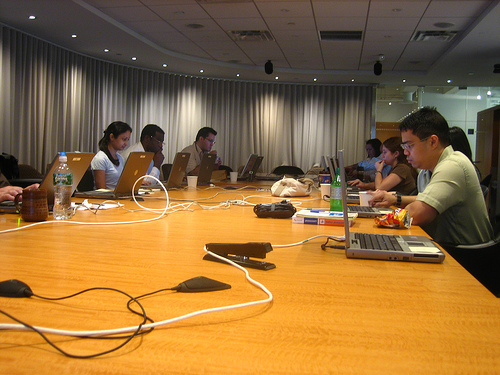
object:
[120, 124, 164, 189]
man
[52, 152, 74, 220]
waterbottle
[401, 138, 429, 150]
glasses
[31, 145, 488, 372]
table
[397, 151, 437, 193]
ground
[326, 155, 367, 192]
laptop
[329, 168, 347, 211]
soda bottle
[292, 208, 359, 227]
book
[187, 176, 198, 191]
coffee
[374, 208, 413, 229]
bag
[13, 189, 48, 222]
cup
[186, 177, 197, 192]
cup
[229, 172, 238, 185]
cup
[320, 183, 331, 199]
cup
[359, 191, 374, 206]
cup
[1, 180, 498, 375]
desk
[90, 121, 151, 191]
woman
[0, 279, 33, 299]
mouse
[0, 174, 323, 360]
ethernet cable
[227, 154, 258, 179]
lap top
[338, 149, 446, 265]
lap top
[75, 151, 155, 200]
lap top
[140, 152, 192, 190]
lap top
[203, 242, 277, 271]
stapler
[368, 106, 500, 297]
man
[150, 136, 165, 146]
eyeglasses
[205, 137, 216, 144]
eyeglasses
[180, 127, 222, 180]
man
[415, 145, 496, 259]
shirt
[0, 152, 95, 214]
lap top